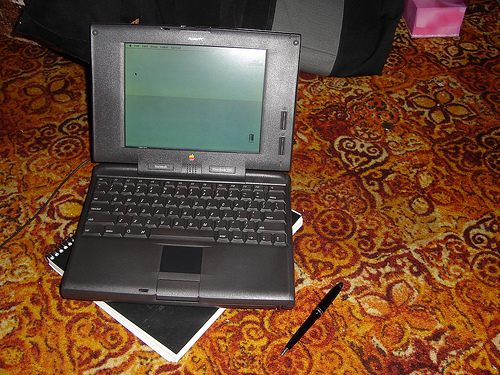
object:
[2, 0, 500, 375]
pattern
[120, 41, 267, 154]
screen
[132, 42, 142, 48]
tab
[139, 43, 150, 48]
tab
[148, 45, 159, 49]
tab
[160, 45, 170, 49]
tab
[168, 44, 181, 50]
tab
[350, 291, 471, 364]
carpet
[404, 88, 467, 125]
design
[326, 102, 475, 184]
carpet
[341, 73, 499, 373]
tiled floor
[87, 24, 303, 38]
line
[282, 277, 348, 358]
pen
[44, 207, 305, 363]
notebook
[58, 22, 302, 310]
laptop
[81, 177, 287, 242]
keyboards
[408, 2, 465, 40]
pink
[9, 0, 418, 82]
bag